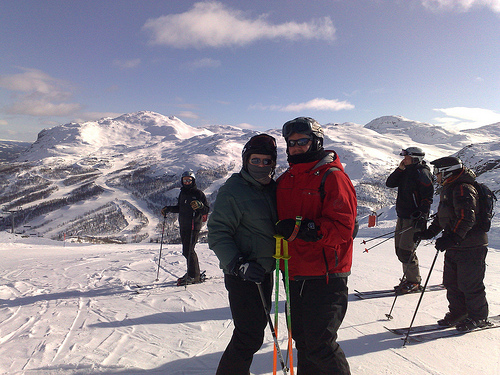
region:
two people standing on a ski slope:
[208, 102, 360, 356]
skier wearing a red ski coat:
[277, 97, 372, 374]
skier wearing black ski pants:
[276, 95, 368, 367]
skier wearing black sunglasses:
[277, 97, 359, 284]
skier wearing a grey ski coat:
[202, 102, 286, 369]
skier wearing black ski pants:
[203, 112, 287, 364]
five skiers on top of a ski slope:
[134, 79, 490, 371]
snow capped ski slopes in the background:
[21, 80, 163, 245]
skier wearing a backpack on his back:
[418, 142, 498, 354]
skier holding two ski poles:
[142, 157, 217, 294]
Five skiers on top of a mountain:
[159, 116, 485, 373]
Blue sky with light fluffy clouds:
[1, 0, 498, 110]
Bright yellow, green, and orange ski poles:
[270, 232, 295, 374]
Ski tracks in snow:
[3, 248, 142, 373]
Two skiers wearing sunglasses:
[206, 112, 353, 374]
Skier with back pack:
[428, 153, 498, 338]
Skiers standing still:
[163, 114, 498, 369]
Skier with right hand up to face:
[384, 142, 436, 293]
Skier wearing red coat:
[271, 113, 356, 373]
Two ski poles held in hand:
[361, 211, 434, 255]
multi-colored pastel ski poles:
[267, 233, 297, 370]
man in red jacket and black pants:
[284, 114, 370, 374]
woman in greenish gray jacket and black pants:
[205, 132, 290, 374]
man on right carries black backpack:
[433, 152, 499, 271]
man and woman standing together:
[197, 115, 367, 373]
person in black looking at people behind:
[157, 170, 210, 290]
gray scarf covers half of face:
[235, 153, 275, 181]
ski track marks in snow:
[0, 238, 221, 373]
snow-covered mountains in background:
[2, 106, 497, 233]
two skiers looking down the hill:
[383, 137, 499, 345]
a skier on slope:
[154, 165, 214, 290]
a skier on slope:
[368, 145, 435, 299]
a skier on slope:
[383, 154, 495, 345]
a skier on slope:
[200, 133, 276, 371]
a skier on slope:
[274, 114, 350, 371]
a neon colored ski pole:
[269, 233, 280, 371]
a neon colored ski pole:
[280, 234, 297, 373]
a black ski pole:
[152, 205, 170, 285]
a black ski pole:
[397, 244, 439, 345]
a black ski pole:
[382, 239, 419, 324]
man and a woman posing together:
[166, 122, 411, 365]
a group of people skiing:
[114, 65, 494, 365]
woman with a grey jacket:
[171, 128, 295, 315]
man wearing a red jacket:
[266, 153, 366, 313]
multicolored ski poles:
[253, 223, 307, 367]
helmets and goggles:
[229, 107, 363, 205]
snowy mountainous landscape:
[16, 63, 485, 316]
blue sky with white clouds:
[23, 9, 478, 144]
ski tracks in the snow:
[10, 247, 253, 359]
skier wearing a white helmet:
[379, 134, 435, 227]